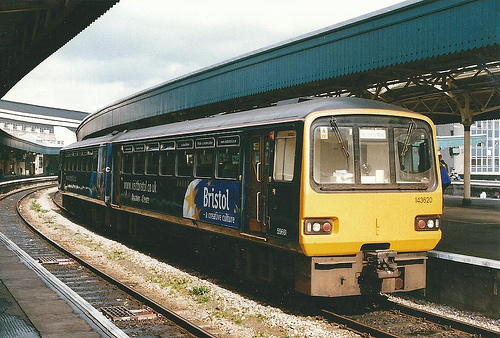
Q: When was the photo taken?
A: Daylight hours.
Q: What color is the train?
A: Yellow and black.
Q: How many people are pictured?
A: One.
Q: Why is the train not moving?
A: It's parked.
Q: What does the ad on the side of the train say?
A: Bristol.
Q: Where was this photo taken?
A: The train station.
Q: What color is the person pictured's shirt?
A: Blue.